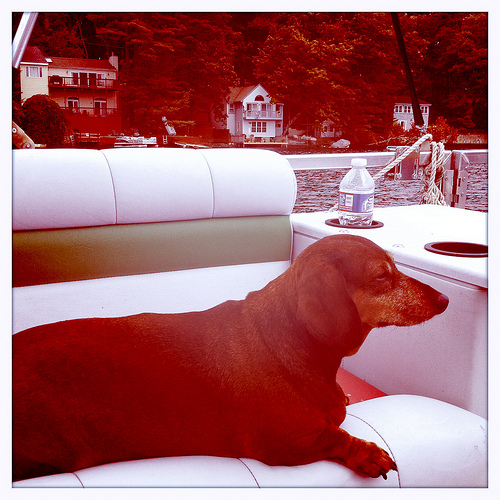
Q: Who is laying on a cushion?
A: A dog.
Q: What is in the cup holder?
A: A water bottle.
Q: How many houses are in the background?
A: Three.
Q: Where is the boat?
A: On the water.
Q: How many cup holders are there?
A: Two.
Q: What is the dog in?
A: A boat.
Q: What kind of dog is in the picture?
A: A dacschund.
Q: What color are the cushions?
A: White and green.